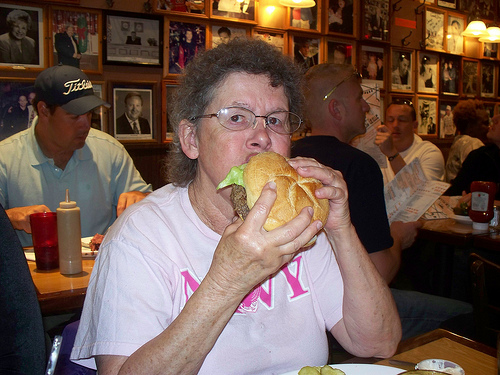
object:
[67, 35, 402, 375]
people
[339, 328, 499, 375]
tables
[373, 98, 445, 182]
man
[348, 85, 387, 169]
menu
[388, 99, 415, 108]
glasses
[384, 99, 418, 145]
head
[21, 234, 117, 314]
table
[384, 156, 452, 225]
menu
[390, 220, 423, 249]
hand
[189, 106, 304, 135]
glasses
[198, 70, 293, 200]
face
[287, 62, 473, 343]
man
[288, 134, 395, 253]
black shirt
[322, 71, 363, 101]
sunglasses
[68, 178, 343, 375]
shirt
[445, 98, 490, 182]
woman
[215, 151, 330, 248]
burger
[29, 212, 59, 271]
cup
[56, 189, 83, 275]
bottle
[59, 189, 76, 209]
lid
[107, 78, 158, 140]
photograph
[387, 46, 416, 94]
photograph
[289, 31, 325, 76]
photograph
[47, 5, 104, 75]
photograph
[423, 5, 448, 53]
photograph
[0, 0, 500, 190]
wall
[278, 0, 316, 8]
light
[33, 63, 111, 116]
cap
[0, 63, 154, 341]
man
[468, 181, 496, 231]
ketchup bottle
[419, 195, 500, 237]
table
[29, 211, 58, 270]
glass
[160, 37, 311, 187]
hair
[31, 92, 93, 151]
head